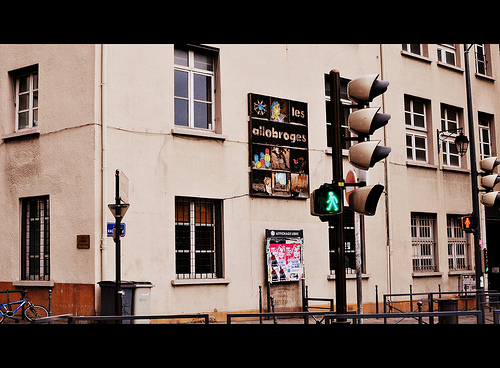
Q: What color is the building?
A: White.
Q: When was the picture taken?
A: During the day.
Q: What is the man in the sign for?
A: To tell pedestrians to walk.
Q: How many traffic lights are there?
A: Two.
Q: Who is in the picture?
A: Nobody.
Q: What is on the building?
A: A sign.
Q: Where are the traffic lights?
A: By the street.